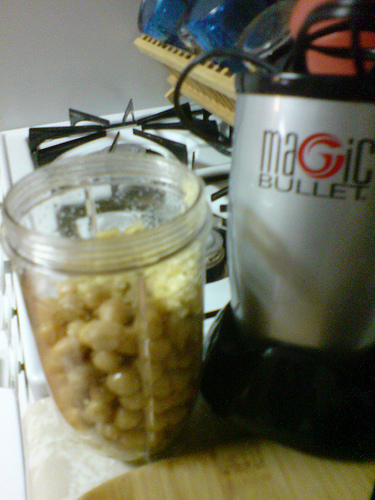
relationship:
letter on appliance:
[263, 125, 279, 173] [201, 28, 374, 467]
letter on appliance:
[259, 125, 283, 172] [189, 13, 372, 429]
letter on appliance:
[280, 129, 299, 180] [189, 13, 372, 429]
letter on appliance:
[342, 133, 357, 187] [189, 13, 372, 429]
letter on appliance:
[350, 134, 373, 191] [189, 13, 372, 429]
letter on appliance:
[256, 172, 272, 195] [189, 13, 372, 429]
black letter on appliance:
[343, 135, 355, 188] [201, 61, 374, 435]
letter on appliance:
[350, 134, 373, 191] [176, 68, 373, 486]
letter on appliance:
[280, 129, 299, 180] [176, 68, 373, 486]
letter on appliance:
[273, 174, 296, 200] [218, 55, 373, 469]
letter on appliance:
[294, 173, 310, 197] [208, 5, 374, 450]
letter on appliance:
[301, 174, 337, 204] [196, 55, 372, 457]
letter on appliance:
[328, 180, 349, 201] [231, 94, 374, 332]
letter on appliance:
[347, 179, 373, 204] [201, 28, 374, 467]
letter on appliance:
[328, 176, 353, 206] [201, 28, 374, 467]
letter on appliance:
[307, 177, 331, 204] [201, 28, 374, 467]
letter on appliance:
[294, 173, 310, 197] [201, 28, 374, 467]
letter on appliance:
[273, 174, 296, 200] [201, 28, 374, 467]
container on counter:
[0, 145, 226, 465] [78, 456, 202, 488]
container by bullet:
[0, 145, 226, 465] [248, 98, 344, 337]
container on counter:
[0, 145, 226, 465] [158, 452, 243, 497]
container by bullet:
[0, 145, 226, 465] [219, 83, 360, 348]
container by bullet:
[0, 145, 226, 465] [241, 128, 343, 270]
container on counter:
[0, 145, 226, 465] [8, 101, 373, 481]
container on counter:
[0, 145, 226, 465] [196, 443, 273, 491]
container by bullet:
[0, 145, 226, 465] [240, 122, 331, 286]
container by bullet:
[0, 145, 226, 465] [202, 65, 367, 416]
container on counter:
[0, 145, 226, 465] [17, 309, 368, 497]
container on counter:
[0, 145, 226, 465] [21, 386, 372, 497]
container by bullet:
[0, 145, 226, 465] [230, 145, 315, 282]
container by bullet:
[0, 145, 226, 465] [193, 67, 374, 455]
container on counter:
[0, 145, 226, 465] [31, 393, 374, 498]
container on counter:
[32, 146, 215, 443] [183, 466, 303, 493]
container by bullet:
[32, 146, 215, 443] [237, 113, 326, 325]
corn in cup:
[76, 315, 144, 381] [100, 290, 175, 366]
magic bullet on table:
[193, 68, 374, 444] [77, 437, 363, 498]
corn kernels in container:
[8, 231, 203, 460] [0, 145, 226, 465]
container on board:
[0, 145, 226, 465] [33, 443, 147, 492]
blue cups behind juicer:
[134, 1, 254, 65] [199, 71, 373, 436]